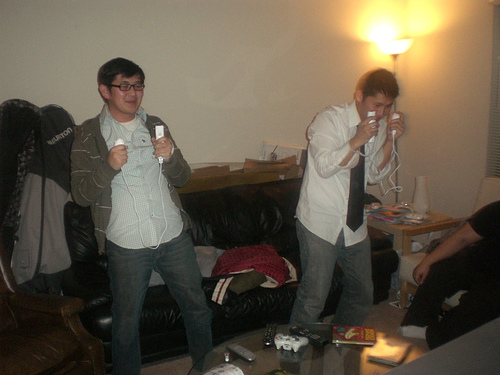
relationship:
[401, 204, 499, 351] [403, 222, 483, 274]
man sitting in a chair arm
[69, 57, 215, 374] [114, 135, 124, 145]
he holding controller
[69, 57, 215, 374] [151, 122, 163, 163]
he holding controller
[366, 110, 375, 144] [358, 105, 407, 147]
controls in hands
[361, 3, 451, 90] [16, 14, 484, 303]
lamp in room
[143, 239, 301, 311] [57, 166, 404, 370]
clothing laying on sofa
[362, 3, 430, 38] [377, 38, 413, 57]
top of lamp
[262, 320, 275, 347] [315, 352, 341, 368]
black remote on table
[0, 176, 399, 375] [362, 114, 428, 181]
couch playing game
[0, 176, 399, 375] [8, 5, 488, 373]
couch in room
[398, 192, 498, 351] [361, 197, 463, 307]
man in front of table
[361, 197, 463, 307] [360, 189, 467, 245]
table with surface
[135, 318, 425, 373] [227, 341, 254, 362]
table with cellphone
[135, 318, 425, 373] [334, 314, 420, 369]
table with books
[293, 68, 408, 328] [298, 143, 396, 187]
man with elbows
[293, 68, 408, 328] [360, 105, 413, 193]
man holding controls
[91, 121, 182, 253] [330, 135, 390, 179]
controls at chest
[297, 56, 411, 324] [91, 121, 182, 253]
man holding controls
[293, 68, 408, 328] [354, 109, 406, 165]
man hiding behind controls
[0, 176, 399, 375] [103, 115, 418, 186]
couch playing game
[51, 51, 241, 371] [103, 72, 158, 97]
he wearing glasses